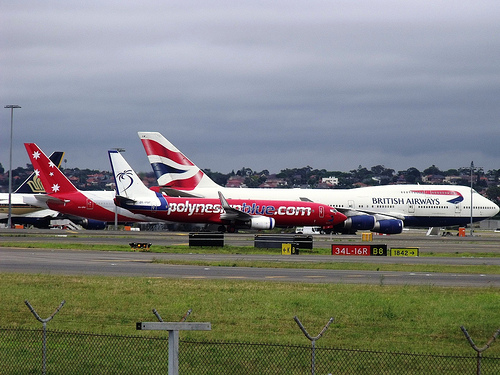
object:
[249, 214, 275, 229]
engine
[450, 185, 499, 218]
cockpit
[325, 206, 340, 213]
cockpit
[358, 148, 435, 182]
ground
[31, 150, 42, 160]
stars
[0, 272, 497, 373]
grass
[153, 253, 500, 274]
grass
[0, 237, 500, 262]
grass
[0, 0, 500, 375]
airport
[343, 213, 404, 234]
engine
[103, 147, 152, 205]
plane tail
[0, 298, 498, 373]
fence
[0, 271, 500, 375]
field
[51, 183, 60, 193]
star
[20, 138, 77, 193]
tail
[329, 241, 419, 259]
markers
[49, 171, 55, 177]
stars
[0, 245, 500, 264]
runway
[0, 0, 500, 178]
sky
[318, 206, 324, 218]
door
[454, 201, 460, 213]
door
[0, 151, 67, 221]
airplane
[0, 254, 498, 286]
asphalt paves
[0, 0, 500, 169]
clouds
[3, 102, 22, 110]
light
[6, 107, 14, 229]
pole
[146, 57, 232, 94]
gray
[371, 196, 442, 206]
name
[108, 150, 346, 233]
airplane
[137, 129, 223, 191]
tail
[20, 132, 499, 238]
airliner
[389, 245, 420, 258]
signs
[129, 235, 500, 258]
fence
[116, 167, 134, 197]
tree